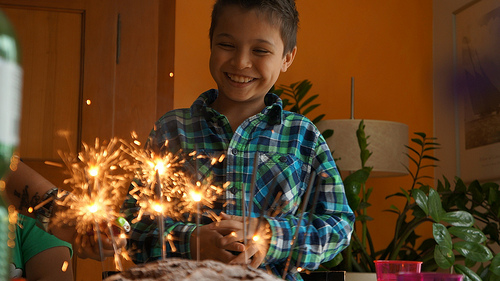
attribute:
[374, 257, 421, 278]
cup —  red,  plastic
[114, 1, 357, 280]
boy — smiling, young, laughing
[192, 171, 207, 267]
sparkler — lit, bright, lit up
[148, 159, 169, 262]
sparkler — lit, bright, lit up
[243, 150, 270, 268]
sparkler — lit, unlit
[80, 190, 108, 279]
sparkler — lit, bright, lit up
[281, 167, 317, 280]
sparkler — lit, unlit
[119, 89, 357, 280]
shirt — blue plaid, plaid, plaid button down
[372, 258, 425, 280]
drinking cup — pink, plastic, red, transparent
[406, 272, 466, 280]
drinking cup — pink, plastic, red, transparent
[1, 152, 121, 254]
arm — tattooed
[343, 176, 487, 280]
house plant — green, large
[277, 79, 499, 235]
house plant — green, large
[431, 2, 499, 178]
artwork — framed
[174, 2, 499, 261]
wall — orange, painted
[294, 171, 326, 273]
sparkler — unlit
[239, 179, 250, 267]
sparkler — unlit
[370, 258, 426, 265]
rim of cup — pink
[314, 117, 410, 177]
shade — tan, cream colored, beige, off white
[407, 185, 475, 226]
leaf — green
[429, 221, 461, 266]
leaf — green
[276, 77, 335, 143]
leaf — green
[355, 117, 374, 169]
leaf — green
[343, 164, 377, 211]
leaf — green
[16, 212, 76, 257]
sleeve — short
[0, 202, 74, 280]
shirt — green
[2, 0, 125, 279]
door — wood, brown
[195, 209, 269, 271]
hands — clasped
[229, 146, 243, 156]
button — blue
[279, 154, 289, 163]
button — blue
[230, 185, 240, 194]
button — blue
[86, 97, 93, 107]
spark — in the air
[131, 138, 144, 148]
spark — in the air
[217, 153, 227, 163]
spark — in the air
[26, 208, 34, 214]
spark — in the air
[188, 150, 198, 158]
spark — in the air